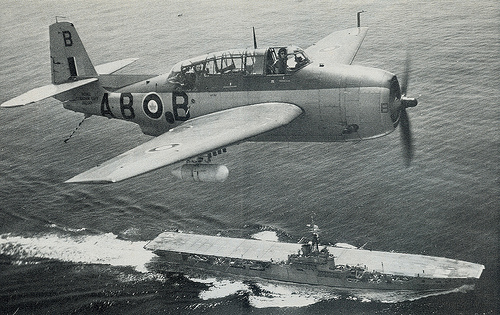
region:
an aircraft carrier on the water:
[142, 216, 487, 298]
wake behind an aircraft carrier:
[0, 217, 150, 272]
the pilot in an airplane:
[270, 45, 290, 71]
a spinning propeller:
[391, 35, 426, 170]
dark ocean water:
[1, 0, 496, 310]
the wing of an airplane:
[61, 98, 301, 188]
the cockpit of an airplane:
[169, 45, 314, 82]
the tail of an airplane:
[43, 19, 100, 109]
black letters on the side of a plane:
[94, 88, 196, 123]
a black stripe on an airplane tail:
[64, 53, 82, 78]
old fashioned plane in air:
[3, 9, 430, 199]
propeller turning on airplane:
[380, 27, 430, 182]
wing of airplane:
[63, 112, 323, 196]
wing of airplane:
[284, 13, 379, 66]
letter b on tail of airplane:
[61, 27, 73, 50]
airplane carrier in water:
[136, 214, 486, 297]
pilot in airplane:
[275, 47, 294, 74]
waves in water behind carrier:
[10, 170, 157, 294]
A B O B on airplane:
[93, 88, 195, 131]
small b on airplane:
[380, 96, 391, 118]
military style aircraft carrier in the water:
[141, 214, 492, 299]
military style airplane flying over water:
[2, 9, 420, 191]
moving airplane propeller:
[390, 42, 422, 170]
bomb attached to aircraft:
[166, 162, 230, 184]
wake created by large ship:
[1, 222, 152, 278]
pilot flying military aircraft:
[268, 46, 290, 74]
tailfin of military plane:
[1, 18, 138, 118]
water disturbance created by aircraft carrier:
[0, 222, 149, 274]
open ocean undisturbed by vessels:
[0, 2, 497, 216]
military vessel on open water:
[141, 211, 489, 299]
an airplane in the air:
[22, 21, 468, 247]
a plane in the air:
[5, 13, 499, 243]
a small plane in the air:
[40, 6, 497, 225]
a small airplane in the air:
[29, 23, 489, 223]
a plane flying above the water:
[19, 16, 499, 215]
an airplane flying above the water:
[39, 18, 494, 283]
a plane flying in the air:
[35, 8, 490, 186]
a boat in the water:
[85, 166, 428, 310]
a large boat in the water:
[139, 176, 478, 307]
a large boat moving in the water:
[119, 187, 492, 314]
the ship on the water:
[131, 218, 473, 313]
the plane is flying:
[17, 11, 473, 223]